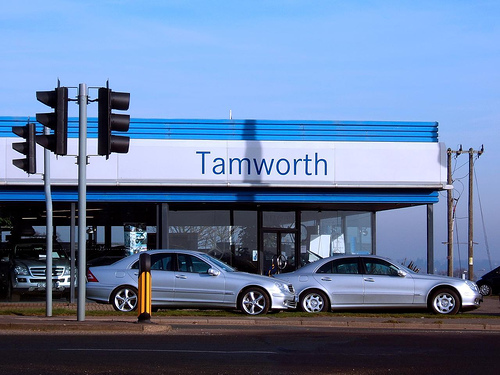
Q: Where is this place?
A: A car lot.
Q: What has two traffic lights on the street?
A: A pole.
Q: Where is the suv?
A: Carport.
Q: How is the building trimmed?
A: Blue.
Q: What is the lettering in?
A: Blue.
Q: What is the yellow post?
A: A divider.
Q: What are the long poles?
A: Power lines.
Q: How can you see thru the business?
A: Glass.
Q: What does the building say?
A: Tamworth.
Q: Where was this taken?
A: Tamworth dealership.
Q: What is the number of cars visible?
A: Four.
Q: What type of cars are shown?
A: Mercedes Benz.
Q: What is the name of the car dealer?
A: Tamworth.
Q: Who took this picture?
A: A customer.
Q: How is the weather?
A: Clear and sunny.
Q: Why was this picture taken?
A: Advertisement.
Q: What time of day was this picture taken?
A: Morning.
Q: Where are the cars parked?
A: By the road.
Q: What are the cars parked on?
A: Grass.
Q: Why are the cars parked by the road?
A: To attract customers.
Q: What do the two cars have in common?
A: Color.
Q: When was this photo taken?
A: Daytime.